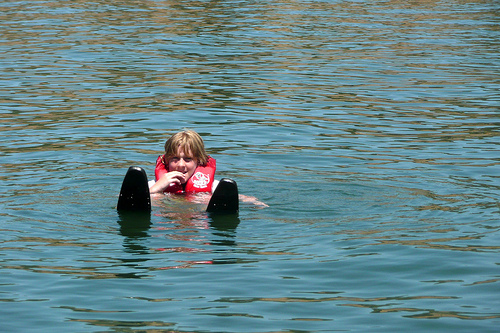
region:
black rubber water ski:
[115, 168, 155, 218]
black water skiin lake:
[209, 181, 239, 215]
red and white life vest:
[153, 154, 216, 194]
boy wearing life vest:
[125, 133, 265, 233]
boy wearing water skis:
[114, 132, 266, 230]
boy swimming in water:
[120, 129, 267, 224]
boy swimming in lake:
[118, 130, 267, 234]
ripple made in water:
[331, 119, 499, 147]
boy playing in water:
[116, 125, 265, 232]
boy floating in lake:
[109, 130, 269, 227]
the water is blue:
[268, 16, 487, 175]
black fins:
[207, 180, 254, 227]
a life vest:
[189, 170, 208, 190]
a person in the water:
[121, 128, 250, 221]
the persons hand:
[165, 168, 185, 188]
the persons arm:
[245, 185, 270, 212]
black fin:
[111, 164, 157, 217]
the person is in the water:
[121, 130, 253, 235]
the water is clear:
[265, 16, 493, 211]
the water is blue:
[56, 13, 366, 113]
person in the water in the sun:
[4, 5, 368, 299]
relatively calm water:
[26, 5, 214, 129]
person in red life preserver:
[146, 129, 219, 198]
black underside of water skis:
[116, 165, 152, 218]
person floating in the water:
[112, 123, 249, 225]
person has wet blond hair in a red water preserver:
[117, 115, 240, 221]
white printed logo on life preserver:
[187, 172, 209, 189]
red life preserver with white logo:
[153, 128, 214, 196]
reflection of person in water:
[157, 196, 206, 236]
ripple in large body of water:
[257, 175, 402, 221]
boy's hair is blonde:
[126, 102, 271, 227]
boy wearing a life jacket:
[135, 146, 245, 206]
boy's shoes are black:
[91, 155, 286, 235]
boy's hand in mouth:
[157, 161, 202, 197]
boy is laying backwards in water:
[107, 111, 249, 236]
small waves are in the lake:
[15, 25, 472, 325]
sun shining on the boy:
[133, 105, 258, 234]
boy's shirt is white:
[139, 157, 161, 194]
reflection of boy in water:
[139, 186, 230, 286]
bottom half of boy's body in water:
[144, 133, 230, 219]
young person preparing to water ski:
[109, 113, 268, 231]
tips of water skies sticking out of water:
[100, 163, 252, 228]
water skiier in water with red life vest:
[103, 121, 263, 241]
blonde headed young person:
[111, 120, 287, 225]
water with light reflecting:
[280, 103, 421, 200]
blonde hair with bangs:
[159, 126, 210, 168]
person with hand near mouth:
[151, 127, 210, 202]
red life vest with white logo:
[153, 154, 223, 193]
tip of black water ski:
[108, 161, 159, 218]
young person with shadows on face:
[158, 129, 208, 190]